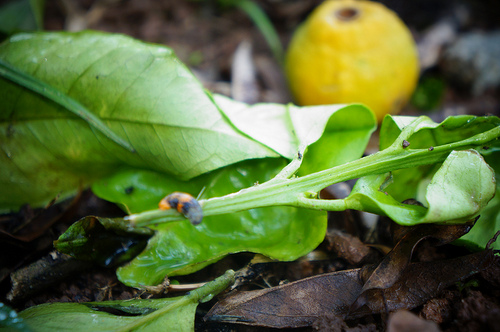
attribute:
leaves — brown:
[247, 247, 352, 307]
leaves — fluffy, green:
[356, 142, 446, 225]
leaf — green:
[187, 86, 491, 250]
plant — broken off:
[4, 22, 496, 330]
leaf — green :
[0, 30, 332, 262]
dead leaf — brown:
[344, 216, 469, 306]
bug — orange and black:
[152, 187, 207, 230]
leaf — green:
[98, 87, 377, 274]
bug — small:
[153, 186, 208, 228]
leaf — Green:
[7, 31, 266, 189]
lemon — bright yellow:
[285, 0, 417, 122]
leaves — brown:
[235, 277, 387, 322]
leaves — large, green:
[6, 38, 462, 268]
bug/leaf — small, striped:
[152, 189, 211, 227]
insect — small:
[158, 187, 207, 227]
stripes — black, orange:
[157, 193, 192, 209]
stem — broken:
[40, 208, 144, 247]